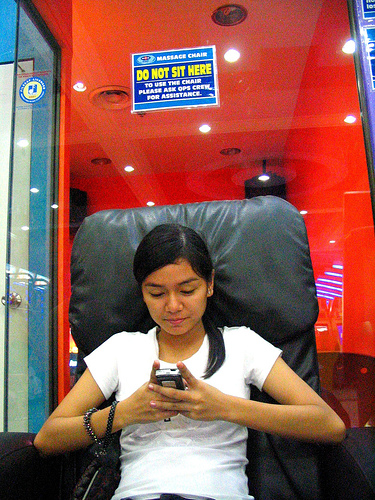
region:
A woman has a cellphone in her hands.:
[143, 358, 216, 407]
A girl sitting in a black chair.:
[83, 228, 291, 477]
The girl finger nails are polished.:
[146, 380, 158, 413]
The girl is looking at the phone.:
[110, 226, 250, 444]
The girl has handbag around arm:
[78, 404, 120, 488]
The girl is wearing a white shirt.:
[99, 338, 268, 498]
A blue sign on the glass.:
[111, 41, 224, 114]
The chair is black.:
[69, 193, 356, 326]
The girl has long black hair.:
[135, 229, 228, 373]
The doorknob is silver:
[5, 285, 34, 316]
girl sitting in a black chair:
[0, 193, 374, 498]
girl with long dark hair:
[119, 216, 233, 384]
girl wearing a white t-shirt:
[31, 210, 345, 498]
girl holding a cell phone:
[27, 225, 351, 498]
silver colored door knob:
[3, 290, 22, 307]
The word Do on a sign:
[135, 68, 150, 82]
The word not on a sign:
[151, 65, 169, 80]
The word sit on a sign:
[171, 62, 186, 78]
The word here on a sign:
[186, 62, 212, 76]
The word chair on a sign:
[187, 51, 208, 57]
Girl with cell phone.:
[30, 190, 369, 490]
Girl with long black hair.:
[108, 228, 291, 398]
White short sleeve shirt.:
[87, 313, 305, 494]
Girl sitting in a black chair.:
[55, 190, 326, 498]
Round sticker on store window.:
[13, 64, 63, 118]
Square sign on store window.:
[122, 45, 239, 122]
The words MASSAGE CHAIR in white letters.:
[151, 48, 213, 61]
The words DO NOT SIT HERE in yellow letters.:
[132, 61, 226, 80]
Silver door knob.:
[2, 281, 33, 320]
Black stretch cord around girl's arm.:
[76, 396, 120, 452]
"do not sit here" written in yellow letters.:
[125, 62, 223, 83]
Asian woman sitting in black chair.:
[100, 198, 243, 488]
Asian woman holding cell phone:
[114, 215, 242, 431]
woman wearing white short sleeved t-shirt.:
[74, 237, 270, 497]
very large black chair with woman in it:
[42, 186, 364, 498]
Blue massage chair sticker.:
[120, 46, 228, 121]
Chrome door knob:
[0, 285, 21, 311]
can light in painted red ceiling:
[218, 43, 246, 73]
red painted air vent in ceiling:
[84, 81, 155, 120]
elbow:
[293, 392, 357, 452]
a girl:
[51, 218, 348, 490]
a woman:
[39, 222, 345, 498]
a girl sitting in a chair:
[40, 203, 353, 499]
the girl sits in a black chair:
[31, 200, 363, 497]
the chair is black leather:
[62, 193, 339, 496]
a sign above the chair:
[133, 47, 217, 105]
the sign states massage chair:
[128, 48, 225, 111]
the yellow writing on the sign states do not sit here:
[129, 46, 221, 113]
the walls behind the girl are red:
[65, 14, 374, 354]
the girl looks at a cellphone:
[39, 206, 352, 490]